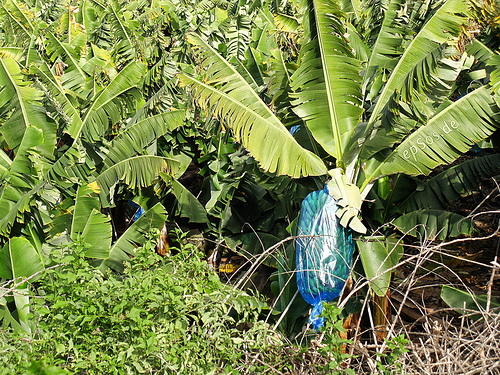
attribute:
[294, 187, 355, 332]
object — full, hanging, plastic, blue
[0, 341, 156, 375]
grass — green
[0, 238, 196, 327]
leaves — green, back, thick, above, banana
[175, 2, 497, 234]
tree — banana, parts, plant, green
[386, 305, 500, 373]
branches — sticks, cornered, bottom, twigs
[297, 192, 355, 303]
bananas — bundled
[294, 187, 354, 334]
bag — reflective, blue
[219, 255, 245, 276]
spot — yellow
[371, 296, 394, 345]
trunk — brown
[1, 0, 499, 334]
vegetation — lush, green